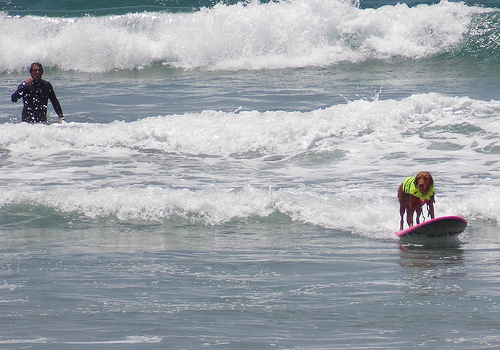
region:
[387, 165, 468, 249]
A DOG ON A SURFBOARD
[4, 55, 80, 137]
A MAN IN THE WATER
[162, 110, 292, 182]
A WAVE IN THE OCEAN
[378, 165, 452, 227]
A WET DOG WEARING A VEST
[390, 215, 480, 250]
PART OF A PINK SURFBOARD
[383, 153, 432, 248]
A GOLDEN RETRIEVER ON A SURFBOARD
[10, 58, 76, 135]
A MAN WEARING A WETSUIT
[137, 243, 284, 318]
PART OF THE OCEAN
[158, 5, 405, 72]
A VERY BIG WAVE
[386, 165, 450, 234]
DOG WEARING YELLOW VEST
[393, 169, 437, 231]
A dog is on a surfboard.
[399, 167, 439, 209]
A dog is wearing a mostly lime-green vest.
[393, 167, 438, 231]
The color of a dog is brown.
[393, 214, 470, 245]
A surfboard is in the water.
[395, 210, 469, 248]
A surfboard is in the ocean.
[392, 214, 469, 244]
The colors of a surfboard are pink and black.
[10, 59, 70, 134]
A man is in the ocean.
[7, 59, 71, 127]
A man is in the water.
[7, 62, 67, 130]
A man is wearing a wetsuit.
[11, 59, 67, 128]
The color of a wetsuit is dark.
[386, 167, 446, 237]
dog on the surfboard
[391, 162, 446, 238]
dog is very wet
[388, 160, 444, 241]
dog on board is brown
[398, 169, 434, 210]
dog wearing a vest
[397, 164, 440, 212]
vest on dog is bright green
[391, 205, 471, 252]
surfboard is light pink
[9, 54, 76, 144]
man standing in water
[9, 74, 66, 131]
man wearing a wetsuit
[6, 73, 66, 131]
mans wetsuit is black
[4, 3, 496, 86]
large wave behind man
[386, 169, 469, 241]
a dog on a surfboard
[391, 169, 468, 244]
a dog on a purple surfboard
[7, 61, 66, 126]
a man in the water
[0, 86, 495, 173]
a white wave in the water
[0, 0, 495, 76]
a white wave in the water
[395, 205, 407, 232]
the leg of a dog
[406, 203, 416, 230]
the leg of a dog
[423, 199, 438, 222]
the leg of a dog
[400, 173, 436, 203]
an inflatable vest on a dog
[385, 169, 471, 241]
a dog surfing on a wave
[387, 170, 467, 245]
a dog surfing on the water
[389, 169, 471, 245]
a dog surfing on a board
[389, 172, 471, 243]
a surfing dog on a board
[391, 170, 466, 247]
a dog surfing on a purple surf board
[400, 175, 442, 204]
a yellow vest on a dog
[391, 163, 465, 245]
a wet dog on a board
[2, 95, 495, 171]
a small wave in the water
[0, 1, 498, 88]
a large wave on the water